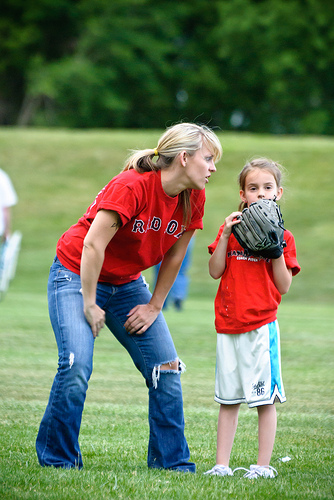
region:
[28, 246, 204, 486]
torn blue jean pants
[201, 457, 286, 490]
white girl's gym shoes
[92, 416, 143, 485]
bright green healthy grass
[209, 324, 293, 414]
blue and silver shorts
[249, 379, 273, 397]
86 number on a short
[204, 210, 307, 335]
red cotton girl's shirt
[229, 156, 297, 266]
girl with a black baseball glove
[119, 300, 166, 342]
hand with blue nail polish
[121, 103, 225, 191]
blond hair with a pony tail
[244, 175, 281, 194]
girl with dark brown eyes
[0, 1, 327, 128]
drooping and curved branches in shade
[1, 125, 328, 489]
grass covered field with slope in back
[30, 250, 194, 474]
denim pants with tears at knees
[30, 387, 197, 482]
wide pant legs covering shoes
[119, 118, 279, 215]
woman giving advice to girl with baseball glove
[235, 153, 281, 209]
girl with dreamy look staring ahead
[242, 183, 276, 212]
mouth hidden by mitt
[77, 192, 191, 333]
woman resting arms on thighs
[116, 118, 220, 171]
hair pulled back in ponytail with bangs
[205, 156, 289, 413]
girl in red shirt with long white shorts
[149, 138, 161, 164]
a yellow hairband in the womans hair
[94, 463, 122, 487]
grass growing on the ground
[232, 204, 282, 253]
a brown baseball glove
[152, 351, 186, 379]
a hole in the womans pants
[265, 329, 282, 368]
a blue stripe on the shorts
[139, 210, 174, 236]
letters on the womans shirt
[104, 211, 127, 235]
a tattoo on the womans arm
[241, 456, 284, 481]
a white tennis shoe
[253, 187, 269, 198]
a nose on the girls face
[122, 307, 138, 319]
blue fingernail polish on the nails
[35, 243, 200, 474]
Woman wearing pants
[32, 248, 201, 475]
Woman is wearing pants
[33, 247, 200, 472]
Woman wearing blue pants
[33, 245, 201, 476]
Woman is wearing blue pants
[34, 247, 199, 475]
Woman wearing jeans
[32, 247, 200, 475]
Woman is wearing jeans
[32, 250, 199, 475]
Woman wearing blue jeans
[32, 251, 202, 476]
Woman is wearing blue jeans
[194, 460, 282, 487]
Girl wearing shoes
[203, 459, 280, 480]
Girl is wearing white shoes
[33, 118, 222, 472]
a blonde woman standing in the grass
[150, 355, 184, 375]
the ripped knee of a woman's jeans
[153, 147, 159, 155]
a yellow elastic band in a woman's hair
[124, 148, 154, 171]
a woman's blonde ponytail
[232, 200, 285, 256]
a girl's baseball glove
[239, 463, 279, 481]
a girl's tennis shoe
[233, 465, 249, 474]
the lace of a tennis shoe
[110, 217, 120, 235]
a tattoo on a woman's arm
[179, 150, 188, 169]
a woman's right ear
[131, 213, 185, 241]
the writing on a woman's t-shirt